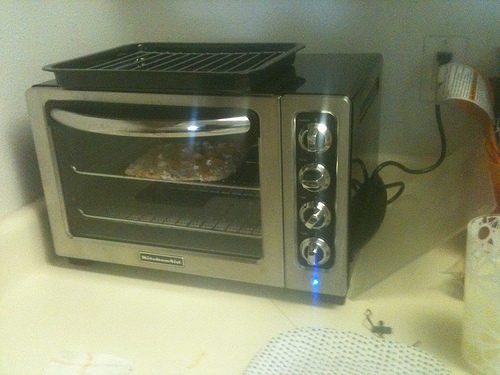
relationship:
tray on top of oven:
[42, 33, 309, 94] [28, 48, 390, 313]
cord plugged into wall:
[371, 69, 451, 208] [377, 41, 490, 160]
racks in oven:
[68, 157, 260, 245] [28, 48, 390, 313]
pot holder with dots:
[235, 322, 450, 374] [331, 350, 356, 360]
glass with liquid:
[463, 212, 499, 369] [479, 339, 493, 346]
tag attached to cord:
[435, 60, 497, 126] [371, 69, 451, 208]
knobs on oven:
[296, 111, 340, 279] [28, 48, 390, 313]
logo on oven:
[137, 253, 187, 267] [28, 48, 390, 313]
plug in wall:
[433, 50, 456, 64] [377, 41, 490, 160]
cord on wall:
[371, 69, 451, 208] [377, 41, 490, 160]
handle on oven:
[49, 104, 252, 146] [28, 48, 390, 313]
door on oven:
[18, 85, 284, 292] [28, 48, 390, 313]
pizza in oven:
[120, 136, 250, 188] [28, 48, 390, 313]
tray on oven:
[42, 33, 309, 94] [28, 48, 390, 313]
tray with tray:
[42, 33, 309, 94] [42, 33, 309, 94]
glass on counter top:
[463, 212, 499, 369] [1, 157, 499, 375]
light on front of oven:
[309, 278, 326, 292] [28, 48, 390, 313]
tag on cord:
[435, 60, 497, 126] [371, 69, 451, 208]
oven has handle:
[28, 48, 390, 313] [49, 104, 252, 146]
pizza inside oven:
[120, 136, 250, 188] [28, 48, 390, 313]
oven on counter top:
[28, 48, 390, 313] [1, 157, 499, 375]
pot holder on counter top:
[235, 322, 450, 374] [1, 157, 499, 375]